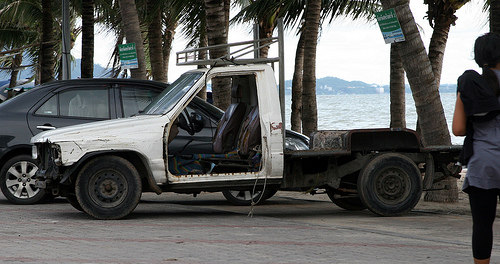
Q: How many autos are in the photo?
A: Two.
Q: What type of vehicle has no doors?
A: Truck.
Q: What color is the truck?
A: White.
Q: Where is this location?
A: Beach.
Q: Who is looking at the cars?
A: Lady.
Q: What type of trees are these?
A: Palm trees.